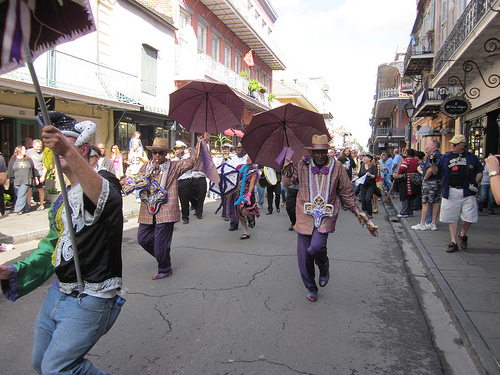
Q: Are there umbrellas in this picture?
A: Yes, there is an umbrella.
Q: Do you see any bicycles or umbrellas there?
A: Yes, there is an umbrella.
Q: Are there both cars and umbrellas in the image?
A: No, there is an umbrella but no cars.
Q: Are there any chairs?
A: No, there are no chairs.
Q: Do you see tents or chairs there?
A: No, there are no chairs or tents.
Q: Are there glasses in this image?
A: No, there are no glasses.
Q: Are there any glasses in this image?
A: No, there are no glasses.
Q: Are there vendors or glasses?
A: No, there are no glasses or vendors.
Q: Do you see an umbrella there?
A: Yes, there is an umbrella.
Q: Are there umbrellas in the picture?
A: Yes, there is an umbrella.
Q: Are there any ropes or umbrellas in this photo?
A: Yes, there is an umbrella.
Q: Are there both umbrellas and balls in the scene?
A: No, there is an umbrella but no balls.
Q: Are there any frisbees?
A: No, there are no frisbees.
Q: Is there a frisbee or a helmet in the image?
A: No, there are no frisbees or helmets.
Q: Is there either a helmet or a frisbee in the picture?
A: No, there are no frisbees or helmets.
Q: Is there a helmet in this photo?
A: No, there are no helmets.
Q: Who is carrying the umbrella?
A: The men are carrying the umbrella.